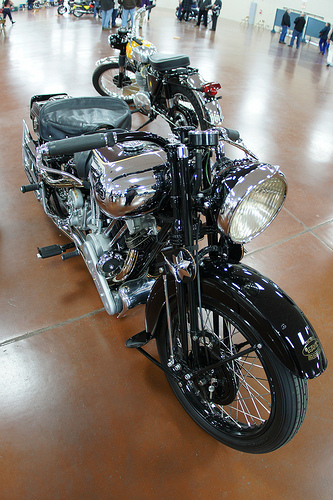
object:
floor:
[0, 6, 332, 498]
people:
[206, 0, 223, 32]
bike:
[91, 0, 224, 149]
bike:
[19, 67, 328, 455]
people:
[97, 0, 113, 32]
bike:
[70, 0, 100, 19]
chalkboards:
[273, 8, 306, 34]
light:
[200, 85, 220, 101]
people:
[286, 11, 307, 50]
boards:
[304, 17, 332, 49]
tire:
[143, 260, 328, 455]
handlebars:
[35, 128, 170, 157]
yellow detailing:
[125, 37, 154, 60]